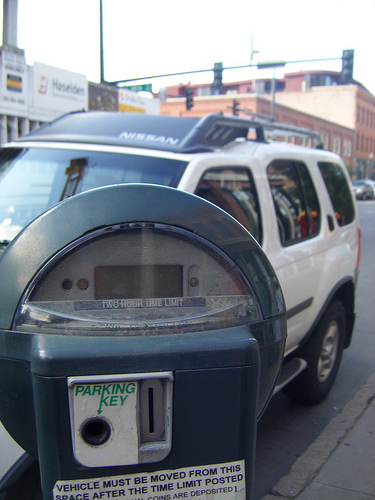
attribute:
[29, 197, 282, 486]
meter — blue, grey, digital, parking, blank, park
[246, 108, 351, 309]
vehicle — white, nissan, suv, parked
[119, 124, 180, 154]
nissan — white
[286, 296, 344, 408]
tire — black, chrome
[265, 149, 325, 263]
window — white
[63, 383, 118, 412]
parking key — green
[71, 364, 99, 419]
words — green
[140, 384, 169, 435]
slot — coin, change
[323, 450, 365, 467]
sidewalk — curb, here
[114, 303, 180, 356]
sign — white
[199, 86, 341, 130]
building — brown